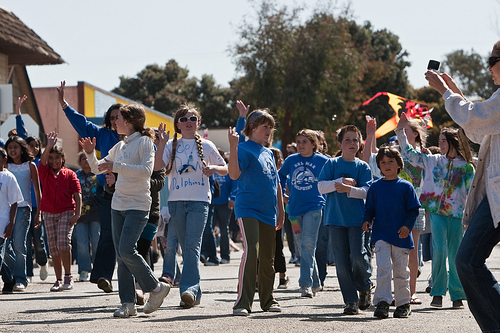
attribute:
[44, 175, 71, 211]
shirt — red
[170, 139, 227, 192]
shirt — white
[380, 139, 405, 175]
hair — dark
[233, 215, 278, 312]
pants — brown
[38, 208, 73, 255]
pants — plaid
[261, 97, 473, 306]
children — group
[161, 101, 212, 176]
hair — brown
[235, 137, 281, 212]
shirt — blue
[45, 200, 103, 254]
pants — plaid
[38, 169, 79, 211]
shirt — red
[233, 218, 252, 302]
stripe — pink